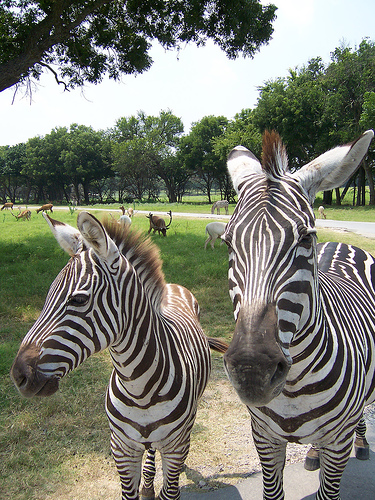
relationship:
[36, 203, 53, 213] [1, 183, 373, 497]
animal grazing on grass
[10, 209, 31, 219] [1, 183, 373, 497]
animal grazing on grass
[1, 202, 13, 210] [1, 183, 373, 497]
animal grazing on grass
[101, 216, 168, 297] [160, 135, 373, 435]
mane of zebra.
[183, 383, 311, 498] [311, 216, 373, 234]
pebbles by side of road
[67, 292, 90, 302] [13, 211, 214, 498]
eyelashes of zebra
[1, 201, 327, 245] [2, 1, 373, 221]
animals in background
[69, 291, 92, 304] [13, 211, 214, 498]
eye of zebra